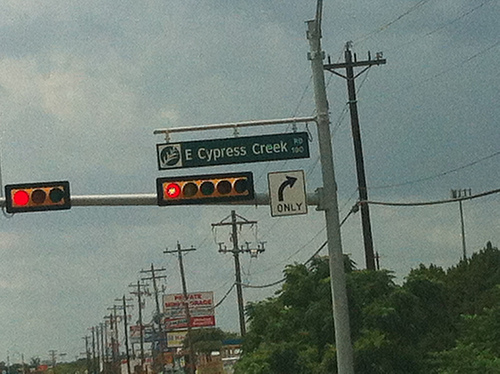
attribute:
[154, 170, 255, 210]
street light — red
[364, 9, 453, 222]
telephone lines — group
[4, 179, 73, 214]
traffic signal — lit red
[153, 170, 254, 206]
traffic signal — lit red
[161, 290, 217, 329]
billboard — white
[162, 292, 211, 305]
lettering — red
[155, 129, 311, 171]
street sign — green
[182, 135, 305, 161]
lettering — white